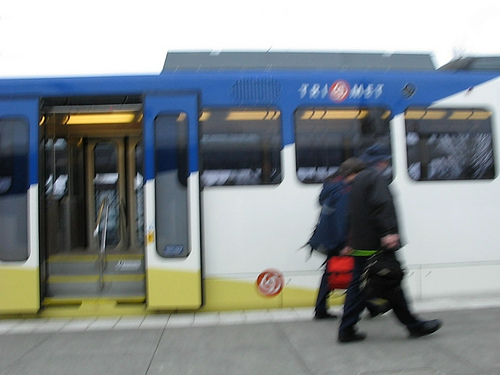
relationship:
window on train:
[175, 99, 296, 190] [2, 45, 473, 347]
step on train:
[13, 248, 144, 323] [2, 45, 473, 347]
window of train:
[175, 99, 296, 190] [2, 45, 473, 347]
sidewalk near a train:
[49, 302, 268, 375] [1, 74, 484, 305]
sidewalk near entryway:
[49, 302, 268, 375] [33, 310, 143, 355]